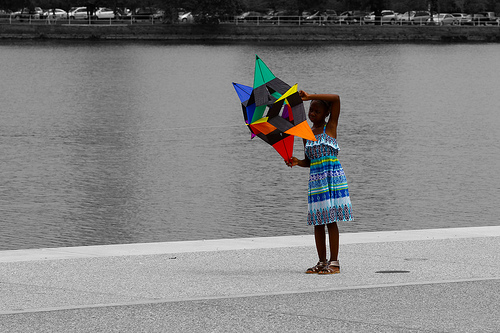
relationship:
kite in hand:
[216, 48, 311, 179] [282, 156, 299, 166]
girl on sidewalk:
[283, 89, 341, 274] [0, 226, 500, 327]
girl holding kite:
[283, 89, 341, 274] [231, 53, 319, 169]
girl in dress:
[283, 89, 341, 274] [302, 117, 355, 226]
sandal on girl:
[305, 261, 326, 272] [283, 89, 341, 274]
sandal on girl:
[314, 259, 341, 273] [283, 89, 341, 274]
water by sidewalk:
[1, 33, 496, 243] [0, 226, 500, 327]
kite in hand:
[231, 53, 319, 169] [284, 156, 299, 166]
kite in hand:
[231, 53, 319, 169] [288, 88, 306, 104]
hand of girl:
[284, 156, 299, 166] [283, 89, 341, 274]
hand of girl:
[288, 88, 306, 104] [283, 89, 341, 274]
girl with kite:
[283, 89, 341, 274] [231, 53, 319, 169]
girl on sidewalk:
[283, 89, 341, 274] [0, 217, 499, 331]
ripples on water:
[66, 83, 153, 205] [1, 33, 496, 243]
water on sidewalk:
[1, 33, 496, 243] [0, 226, 500, 327]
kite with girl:
[231, 53, 319, 169] [283, 89, 341, 274]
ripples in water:
[63, 45, 169, 247] [1, 33, 496, 243]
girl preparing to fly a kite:
[283, 89, 341, 274] [231, 53, 319, 169]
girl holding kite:
[261, 87, 375, 264] [231, 53, 319, 169]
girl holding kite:
[283, 89, 341, 274] [222, 40, 317, 163]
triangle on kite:
[283, 120, 321, 145] [231, 53, 319, 169]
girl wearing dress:
[283, 89, 341, 274] [302, 117, 352, 227]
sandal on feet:
[316, 259, 341, 274] [308, 266, 337, 275]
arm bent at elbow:
[312, 92, 341, 138] [328, 92, 340, 106]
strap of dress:
[320, 119, 331, 134] [306, 144, 354, 226]